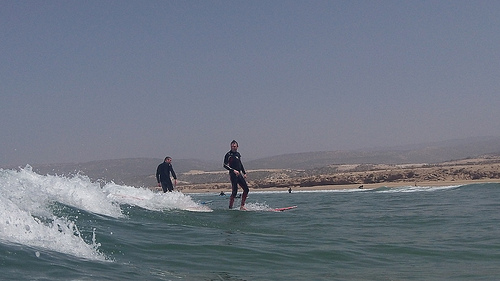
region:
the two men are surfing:
[145, 126, 275, 221]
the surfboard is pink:
[238, 196, 317, 227]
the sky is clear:
[76, 49, 444, 122]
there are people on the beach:
[317, 171, 472, 188]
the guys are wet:
[158, 150, 262, 205]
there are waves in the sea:
[64, 176, 256, 275]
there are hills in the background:
[275, 128, 486, 149]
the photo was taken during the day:
[11, 10, 488, 278]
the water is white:
[21, 183, 50, 245]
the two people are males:
[153, 125, 302, 235]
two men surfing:
[108, 76, 298, 261]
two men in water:
[114, 136, 357, 271]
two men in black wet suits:
[134, 103, 271, 244]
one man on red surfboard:
[208, 100, 315, 251]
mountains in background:
[37, 143, 462, 211]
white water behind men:
[0, 139, 265, 279]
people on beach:
[208, 171, 462, 211]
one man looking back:
[196, 127, 310, 228]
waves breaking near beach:
[279, 162, 494, 232]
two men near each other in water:
[103, 133, 310, 225]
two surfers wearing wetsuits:
[135, 121, 309, 213]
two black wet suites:
[144, 126, 259, 215]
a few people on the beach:
[163, 178, 476, 195]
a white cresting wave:
[0, 161, 239, 278]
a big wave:
[0, 149, 220, 279]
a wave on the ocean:
[1, 138, 302, 278]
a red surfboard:
[256, 196, 318, 218]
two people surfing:
[128, 121, 313, 227]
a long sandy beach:
[139, 172, 497, 198]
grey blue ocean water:
[3, 116, 495, 278]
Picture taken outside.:
[19, 17, 494, 227]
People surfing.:
[110, 118, 314, 237]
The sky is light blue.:
[110, 25, 340, 87]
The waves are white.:
[25, 164, 122, 270]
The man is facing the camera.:
[219, 132, 269, 224]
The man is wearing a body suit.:
[204, 123, 274, 274]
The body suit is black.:
[214, 127, 269, 220]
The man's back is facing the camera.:
[152, 150, 192, 233]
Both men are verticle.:
[147, 146, 297, 200]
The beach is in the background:
[290, 156, 426, 207]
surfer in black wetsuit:
[221, 144, 257, 209]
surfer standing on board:
[153, 157, 178, 199]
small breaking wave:
[6, 173, 134, 257]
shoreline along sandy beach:
[276, 156, 492, 191]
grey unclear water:
[315, 220, 479, 272]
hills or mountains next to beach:
[274, 146, 494, 159]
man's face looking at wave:
[223, 137, 241, 152]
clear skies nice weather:
[40, 26, 499, 141]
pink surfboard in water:
[231, 202, 298, 213]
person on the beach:
[286, 185, 296, 202]